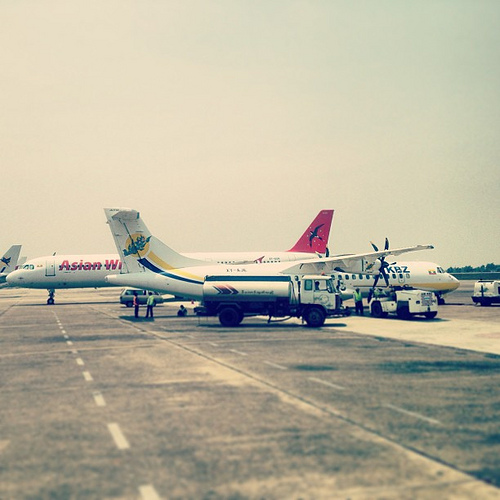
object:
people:
[133, 292, 155, 319]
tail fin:
[287, 209, 336, 252]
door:
[45, 261, 55, 277]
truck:
[202, 272, 342, 327]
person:
[133, 293, 140, 319]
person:
[144, 292, 155, 318]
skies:
[1, 0, 498, 268]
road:
[4, 300, 498, 498]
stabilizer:
[288, 207, 334, 256]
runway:
[0, 300, 499, 500]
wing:
[277, 244, 435, 274]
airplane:
[102, 205, 460, 317]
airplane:
[4, 208, 333, 318]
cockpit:
[17, 261, 44, 285]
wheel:
[397, 303, 412, 320]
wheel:
[371, 300, 389, 317]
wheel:
[126, 301, 133, 308]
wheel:
[47, 298, 55, 305]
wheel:
[218, 306, 245, 326]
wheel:
[304, 307, 327, 327]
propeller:
[370, 238, 390, 288]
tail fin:
[103, 207, 217, 272]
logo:
[203, 275, 292, 297]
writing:
[58, 259, 122, 270]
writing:
[386, 265, 411, 273]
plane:
[0, 245, 23, 274]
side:
[23, 262, 108, 281]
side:
[331, 265, 441, 283]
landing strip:
[1, 292, 484, 497]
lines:
[49, 306, 163, 498]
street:
[0, 330, 499, 499]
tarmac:
[14, 305, 469, 499]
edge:
[383, 260, 435, 262]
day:
[0, 1, 484, 494]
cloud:
[0, 3, 484, 269]